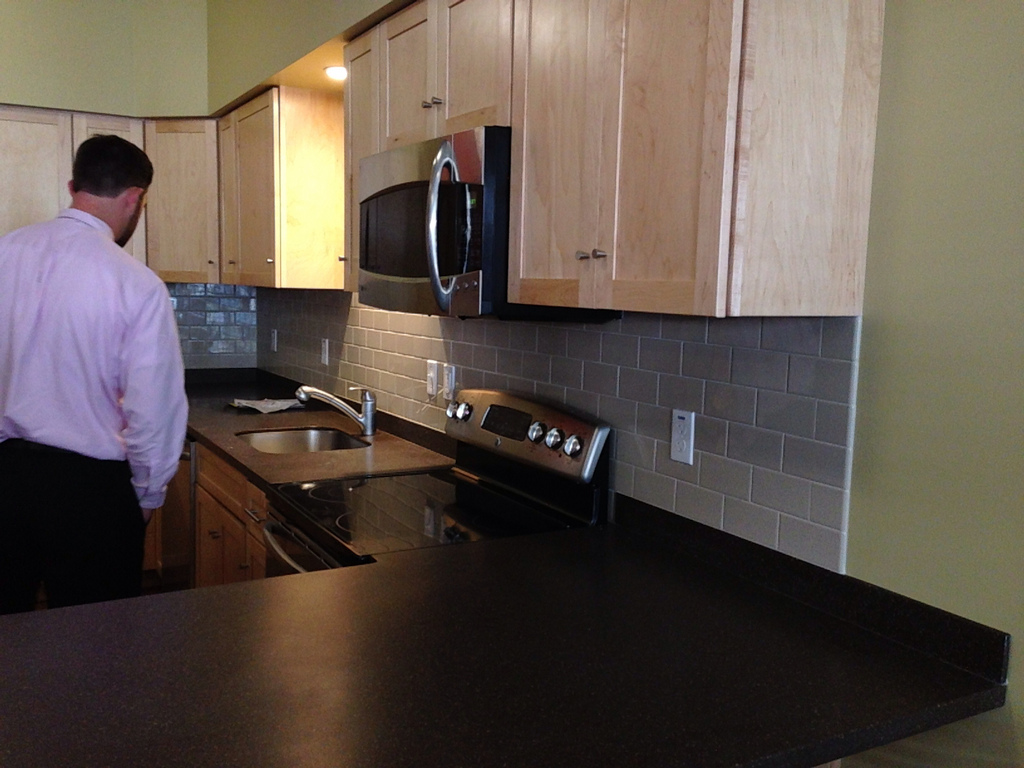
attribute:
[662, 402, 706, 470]
outlet — white electric 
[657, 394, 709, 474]
switch — white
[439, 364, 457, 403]
switch — white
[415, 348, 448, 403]
switch — white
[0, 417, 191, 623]
pants — black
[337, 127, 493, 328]
microwave — mounted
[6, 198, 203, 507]
shirt — pink , purple, white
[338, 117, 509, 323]
microwave — silver, black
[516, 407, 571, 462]
stove knobs — small, gray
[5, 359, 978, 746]
counter top — black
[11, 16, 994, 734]
kitchen — clean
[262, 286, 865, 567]
tiles — gray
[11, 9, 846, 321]
cabinets — wooden, light brown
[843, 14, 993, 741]
wall — light green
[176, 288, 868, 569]
backsplash — grey, brick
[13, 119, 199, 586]
man — standing up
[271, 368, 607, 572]
range — black, silver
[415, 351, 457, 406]
switches — white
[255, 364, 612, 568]
stove — black, silver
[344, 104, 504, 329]
microwave — silver, black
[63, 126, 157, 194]
hair — short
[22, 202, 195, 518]
shirt — purple, pink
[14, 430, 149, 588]
pants — black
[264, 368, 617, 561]
oven — black, silver